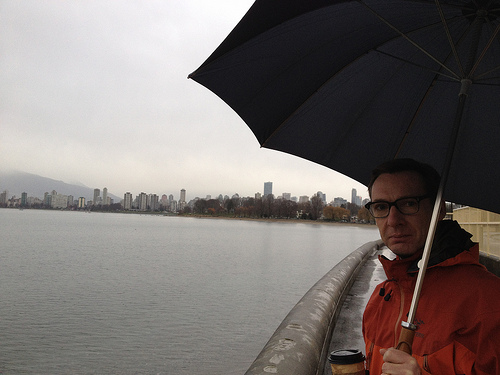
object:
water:
[84, 264, 137, 290]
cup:
[325, 348, 365, 375]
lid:
[327, 349, 364, 365]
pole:
[407, 288, 421, 319]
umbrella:
[187, 0, 500, 215]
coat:
[360, 219, 499, 375]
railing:
[243, 286, 338, 375]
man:
[361, 158, 499, 375]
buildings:
[0, 191, 7, 208]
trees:
[246, 200, 263, 218]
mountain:
[2, 171, 96, 195]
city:
[0, 180, 372, 225]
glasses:
[365, 196, 429, 218]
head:
[369, 158, 446, 255]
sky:
[1, 0, 138, 38]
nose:
[387, 206, 406, 227]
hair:
[368, 158, 441, 208]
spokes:
[352, 0, 500, 85]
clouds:
[97, 90, 133, 107]